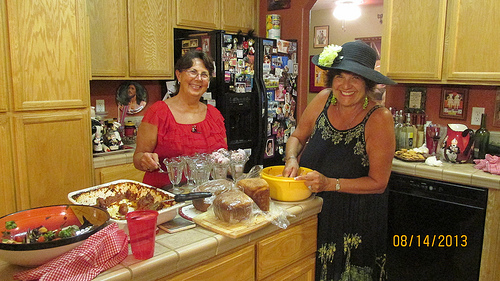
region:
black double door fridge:
[167, 6, 338, 178]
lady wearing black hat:
[309, 18, 399, 112]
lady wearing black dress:
[289, 67, 432, 279]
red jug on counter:
[435, 106, 478, 171]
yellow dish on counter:
[242, 142, 326, 219]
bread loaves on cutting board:
[167, 165, 305, 268]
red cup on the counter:
[109, 202, 189, 271]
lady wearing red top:
[122, 86, 247, 183]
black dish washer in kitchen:
[370, 168, 499, 279]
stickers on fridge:
[221, 30, 313, 170]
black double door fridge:
[162, 13, 331, 165]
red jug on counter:
[431, 102, 482, 190]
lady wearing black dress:
[264, 58, 446, 280]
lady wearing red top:
[123, 73, 244, 187]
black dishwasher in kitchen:
[387, 166, 498, 279]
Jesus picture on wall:
[106, 73, 168, 127]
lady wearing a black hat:
[291, 18, 406, 114]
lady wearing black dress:
[281, 90, 416, 277]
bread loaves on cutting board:
[155, 167, 275, 244]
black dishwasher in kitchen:
[385, 160, 495, 275]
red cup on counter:
[120, 195, 170, 261]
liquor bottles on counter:
[390, 95, 445, 170]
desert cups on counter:
[155, 135, 255, 186]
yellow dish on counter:
[250, 155, 330, 212]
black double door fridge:
[174, 27, 324, 179]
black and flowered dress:
[288, 73, 392, 278]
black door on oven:
[378, 164, 485, 279]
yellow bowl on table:
[241, 154, 328, 202]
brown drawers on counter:
[198, 227, 315, 279]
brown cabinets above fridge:
[7, 3, 291, 113]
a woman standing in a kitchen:
[132, 51, 227, 183]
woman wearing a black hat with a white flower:
[308, 40, 398, 88]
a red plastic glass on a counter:
[124, 210, 159, 257]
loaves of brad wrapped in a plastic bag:
[193, 178, 251, 224]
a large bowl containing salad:
[0, 204, 109, 264]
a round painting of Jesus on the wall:
[116, 82, 148, 112]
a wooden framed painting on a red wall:
[438, 86, 470, 121]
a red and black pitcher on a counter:
[443, 120, 473, 162]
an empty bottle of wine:
[473, 110, 490, 161]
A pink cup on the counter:
[123, 206, 158, 258]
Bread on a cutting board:
[212, 192, 252, 224]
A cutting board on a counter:
[192, 205, 271, 240]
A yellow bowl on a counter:
[257, 162, 319, 201]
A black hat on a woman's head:
[311, 40, 392, 87]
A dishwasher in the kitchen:
[382, 170, 489, 279]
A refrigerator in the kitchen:
[174, 27, 299, 172]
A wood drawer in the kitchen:
[254, 217, 318, 279]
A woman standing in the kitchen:
[282, 40, 394, 279]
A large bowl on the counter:
[0, 203, 110, 268]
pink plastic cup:
[125, 209, 156, 259]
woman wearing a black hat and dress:
[283, 38, 393, 279]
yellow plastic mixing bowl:
[261, 164, 314, 200]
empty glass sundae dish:
[164, 155, 184, 190]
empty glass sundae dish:
[181, 155, 191, 180]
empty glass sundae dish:
[192, 157, 210, 183]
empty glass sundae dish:
[213, 155, 227, 180]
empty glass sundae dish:
[228, 153, 245, 178]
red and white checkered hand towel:
[23, 223, 128, 278]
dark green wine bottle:
[473, 110, 490, 155]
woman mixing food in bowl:
[283, 30, 404, 280]